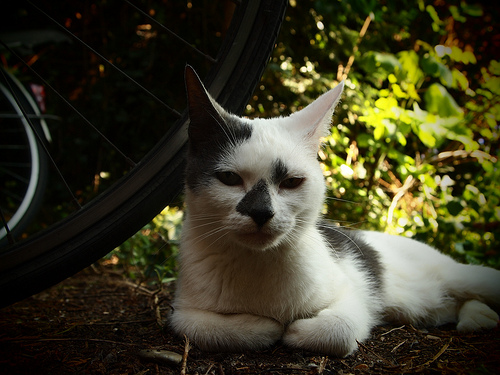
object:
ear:
[296, 82, 348, 145]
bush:
[0, 0, 500, 287]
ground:
[0, 259, 500, 374]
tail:
[447, 263, 499, 295]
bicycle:
[0, 0, 290, 309]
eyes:
[274, 175, 308, 191]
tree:
[123, 0, 500, 229]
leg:
[173, 305, 249, 352]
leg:
[311, 294, 374, 357]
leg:
[458, 294, 489, 310]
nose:
[245, 184, 278, 220]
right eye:
[211, 170, 244, 187]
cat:
[170, 63, 500, 360]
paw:
[454, 301, 500, 336]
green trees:
[264, 0, 500, 263]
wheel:
[0, 0, 280, 313]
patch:
[235, 177, 276, 226]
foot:
[454, 298, 494, 333]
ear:
[185, 64, 240, 151]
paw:
[283, 316, 316, 352]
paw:
[236, 313, 280, 349]